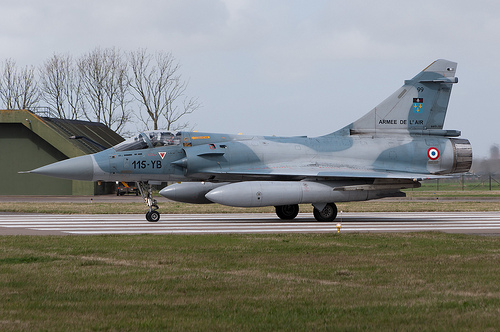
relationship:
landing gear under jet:
[137, 180, 338, 221] [18, 59, 474, 223]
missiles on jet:
[157, 181, 423, 210] [18, 59, 474, 223]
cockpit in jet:
[111, 130, 183, 152] [18, 59, 474, 223]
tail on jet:
[323, 60, 457, 134] [18, 59, 474, 223]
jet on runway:
[18, 59, 474, 223] [0, 210, 500, 234]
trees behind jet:
[0, 45, 200, 141] [18, 59, 474, 223]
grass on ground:
[1, 182, 499, 331] [0, 182, 500, 331]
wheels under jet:
[146, 201, 337, 222] [18, 59, 474, 223]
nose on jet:
[19, 165, 49, 177] [18, 59, 474, 223]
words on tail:
[378, 118, 424, 126] [323, 60, 457, 134]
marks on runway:
[0, 210, 499, 232] [0, 210, 500, 234]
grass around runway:
[1, 182, 499, 331] [0, 210, 500, 234]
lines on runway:
[0, 210, 499, 237] [0, 210, 500, 234]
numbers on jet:
[132, 159, 147, 169] [18, 59, 474, 223]